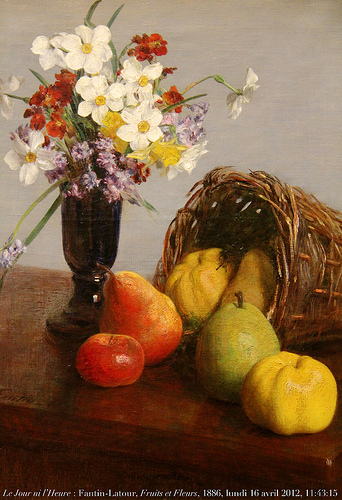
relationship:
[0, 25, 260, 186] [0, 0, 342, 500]
daisy in painting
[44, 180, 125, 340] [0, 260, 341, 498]
vase on table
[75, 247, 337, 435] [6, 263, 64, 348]
fruit on table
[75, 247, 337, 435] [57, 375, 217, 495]
fruit on table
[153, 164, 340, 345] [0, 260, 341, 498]
basket on table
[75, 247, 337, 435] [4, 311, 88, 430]
fruit on table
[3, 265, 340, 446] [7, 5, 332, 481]
table in a painting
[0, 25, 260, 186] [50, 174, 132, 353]
daisy in vase